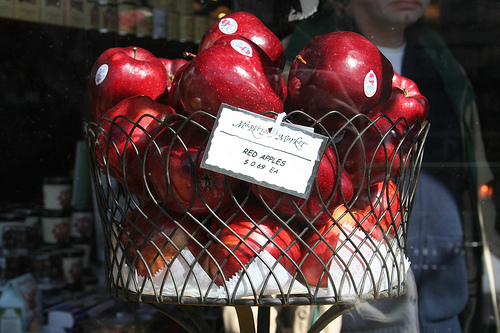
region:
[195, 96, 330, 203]
a price tag for red apples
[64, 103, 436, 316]
a wire display basket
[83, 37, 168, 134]
red apple with a sticker on it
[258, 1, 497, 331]
a man standing behind the basket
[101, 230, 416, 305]
a paper liner in the basket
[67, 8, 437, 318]
red apples displayed in a basket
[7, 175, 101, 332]
other items for sale in the background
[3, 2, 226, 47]
items on a high shelf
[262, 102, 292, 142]
a tie strap holding the tag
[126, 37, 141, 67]
an apple stem on the apple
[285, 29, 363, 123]
red apple in basket with white tag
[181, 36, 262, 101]
red apple in basket with white tag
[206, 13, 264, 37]
red apple in basket with white tag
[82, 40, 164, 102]
red apple in basket with white tag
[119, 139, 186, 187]
red apple in basket with white tag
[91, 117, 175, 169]
red apple in basket with white tag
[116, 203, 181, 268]
red apple in basket with white tag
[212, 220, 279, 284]
red apple in basket with white tag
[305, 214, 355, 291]
red apple in basket with white tag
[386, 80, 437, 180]
red apple in basket with white tag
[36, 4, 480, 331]
a bowl of apples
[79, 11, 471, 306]
a bowl of fed apples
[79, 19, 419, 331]
red apples in a bowl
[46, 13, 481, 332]
apples in a bowl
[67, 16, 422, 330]
apples that are in a pile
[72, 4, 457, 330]
red apples in a pile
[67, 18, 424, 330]
apples on display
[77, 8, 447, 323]
red apples on display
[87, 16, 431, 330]
apples for sale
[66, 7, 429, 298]
red apples for sale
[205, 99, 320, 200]
a small white and black sign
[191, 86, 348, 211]
a sign selling red apples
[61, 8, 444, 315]
a basket full of fruit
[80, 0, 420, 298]
fourteen red apples in a basket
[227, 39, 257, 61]
the white sticker on an apple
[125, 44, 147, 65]
the brown stem of an apple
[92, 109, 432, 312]
a black wire basket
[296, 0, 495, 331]
a man in the background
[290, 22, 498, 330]
a person wearing a black jacket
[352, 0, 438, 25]
a frowning mouth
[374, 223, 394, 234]
part of a grill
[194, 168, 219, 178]
part of an apple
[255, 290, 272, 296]
edge of an apple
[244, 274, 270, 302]
bottom of a basket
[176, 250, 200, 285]
side of a basket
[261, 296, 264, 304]
tip of a basket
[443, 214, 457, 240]
part of a mirror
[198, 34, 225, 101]
side of an apple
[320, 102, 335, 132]
part of an apple